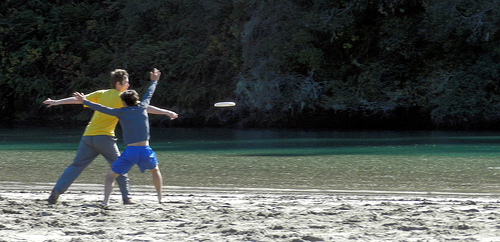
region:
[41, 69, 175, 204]
man in a yellow t-shirt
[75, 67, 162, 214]
boy on a gray shirt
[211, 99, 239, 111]
white frisbee in the air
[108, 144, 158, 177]
blue shorts on the boy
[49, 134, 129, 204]
gray pants on the man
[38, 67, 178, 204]
two people playing with a frisbee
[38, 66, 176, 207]
two people playing on the beach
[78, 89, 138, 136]
yellow shirt on the man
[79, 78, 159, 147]
gray shirt on the boy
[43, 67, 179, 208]
two people playing next to the water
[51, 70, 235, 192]
people playing frisbee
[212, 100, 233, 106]
a white frisbee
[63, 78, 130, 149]
a person in a yellow shirt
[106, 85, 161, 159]
a person in blue shirt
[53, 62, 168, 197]
people on the beach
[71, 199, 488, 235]
the sand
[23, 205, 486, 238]
tracks in the sand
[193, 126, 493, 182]
water in front of the people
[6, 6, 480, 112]
trees behind the water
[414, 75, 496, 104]
leaves on the tree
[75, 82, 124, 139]
the shirt is yellow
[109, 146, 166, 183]
the short is blue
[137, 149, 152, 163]
the shorts are blue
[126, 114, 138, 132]
the shirt is gray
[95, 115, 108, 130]
the shirt is yellow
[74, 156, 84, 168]
the pants are gray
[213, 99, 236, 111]
the frisbee is white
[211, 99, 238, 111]
the frisbee is in the air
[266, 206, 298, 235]
the sand is clumpy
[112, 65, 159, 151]
he is blocking the taller guy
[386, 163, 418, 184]
the water is brown green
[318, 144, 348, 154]
the water is teal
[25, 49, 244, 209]
the men playing frisbee on the sand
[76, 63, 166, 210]
the man guarding the other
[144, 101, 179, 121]
the mans outstretched arm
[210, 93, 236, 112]
the white frisbee in the wair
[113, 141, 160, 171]
the blue pair of shorts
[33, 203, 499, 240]
the lumps of sand on the beach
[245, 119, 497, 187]
the still water behind the men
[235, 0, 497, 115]
the trees along the eaters edge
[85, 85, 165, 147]
the blue long sleeve shirt on the man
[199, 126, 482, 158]
the shadows on top of the water